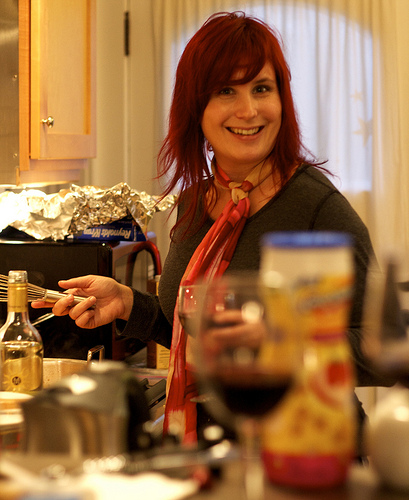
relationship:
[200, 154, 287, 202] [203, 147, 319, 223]
scarf on neck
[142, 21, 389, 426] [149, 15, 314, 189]
woman has head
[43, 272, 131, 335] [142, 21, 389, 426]
hand of woman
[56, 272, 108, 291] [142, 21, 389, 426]
thumb of woman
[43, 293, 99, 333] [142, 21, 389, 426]
finger of woman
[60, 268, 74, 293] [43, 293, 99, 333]
nail on finger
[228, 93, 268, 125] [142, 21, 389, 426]
nose of woman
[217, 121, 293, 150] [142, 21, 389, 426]
mouth of woman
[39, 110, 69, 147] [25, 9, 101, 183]
handle of cabinet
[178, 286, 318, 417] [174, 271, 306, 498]
wine in glass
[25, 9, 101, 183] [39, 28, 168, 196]
cabinet on wall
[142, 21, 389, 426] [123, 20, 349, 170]
woman with hair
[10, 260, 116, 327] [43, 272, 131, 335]
whisk in hand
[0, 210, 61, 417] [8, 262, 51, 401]
oil in bottle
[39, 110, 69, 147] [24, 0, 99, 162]
handle on cabinet